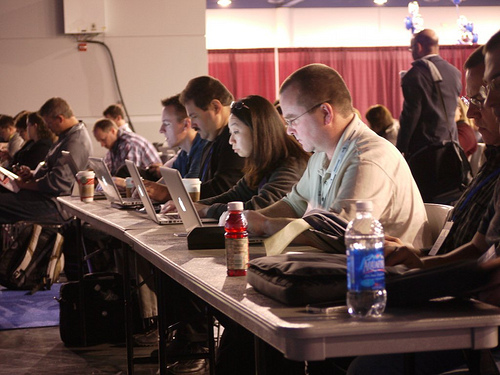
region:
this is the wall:
[130, 25, 180, 62]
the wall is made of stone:
[129, 18, 184, 53]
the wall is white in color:
[119, 17, 171, 54]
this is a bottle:
[348, 200, 385, 307]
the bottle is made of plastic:
[337, 205, 399, 322]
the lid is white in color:
[359, 199, 373, 212]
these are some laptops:
[90, 153, 207, 236]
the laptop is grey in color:
[166, 175, 178, 183]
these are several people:
[24, 94, 466, 213]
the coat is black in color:
[422, 93, 446, 120]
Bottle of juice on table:
[221, 199, 250, 276]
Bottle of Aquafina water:
[341, 197, 388, 321]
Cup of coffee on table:
[75, 167, 97, 204]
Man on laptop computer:
[87, 93, 199, 211]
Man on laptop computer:
[122, 73, 249, 226]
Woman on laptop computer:
[125, 93, 310, 231]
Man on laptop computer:
[159, 63, 434, 254]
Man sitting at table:
[303, 46, 498, 271]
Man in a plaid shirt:
[90, 116, 168, 184]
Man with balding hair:
[391, 28, 464, 192]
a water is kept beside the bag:
[244, 200, 389, 335]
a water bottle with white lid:
[344, 200, 390, 322]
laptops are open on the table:
[85, 158, 238, 255]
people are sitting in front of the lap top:
[89, 65, 433, 342]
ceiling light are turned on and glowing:
[200, 0, 482, 32]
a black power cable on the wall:
[75, 39, 153, 104]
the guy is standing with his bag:
[391, 28, 475, 204]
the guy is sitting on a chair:
[6, 95, 85, 288]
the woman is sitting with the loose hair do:
[164, 95, 304, 212]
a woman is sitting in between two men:
[149, 63, 433, 290]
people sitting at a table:
[56, 38, 498, 370]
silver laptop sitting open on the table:
[150, 165, 289, 252]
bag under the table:
[44, 263, 154, 353]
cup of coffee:
[73, 169, 103, 209]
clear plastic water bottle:
[330, 196, 405, 322]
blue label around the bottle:
[338, 240, 395, 295]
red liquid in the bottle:
[213, 199, 255, 277]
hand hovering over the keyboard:
[154, 193, 214, 220]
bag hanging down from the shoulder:
[391, 52, 472, 202]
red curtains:
[205, 46, 498, 143]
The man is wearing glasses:
[283, 99, 329, 127]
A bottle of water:
[345, 199, 387, 316]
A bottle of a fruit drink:
[224, 201, 249, 272]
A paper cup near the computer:
[75, 169, 96, 199]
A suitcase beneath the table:
[61, 270, 130, 346]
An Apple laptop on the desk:
[159, 167, 265, 242]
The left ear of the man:
[321, 102, 330, 128]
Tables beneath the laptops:
[55, 194, 497, 360]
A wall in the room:
[1, 1, 206, 157]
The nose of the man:
[286, 120, 296, 137]